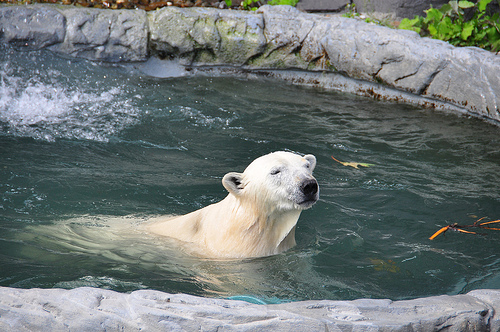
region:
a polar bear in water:
[14, 17, 488, 325]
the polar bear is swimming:
[36, 120, 356, 281]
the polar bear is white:
[89, 144, 331, 265]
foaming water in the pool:
[3, 51, 159, 166]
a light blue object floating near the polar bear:
[217, 275, 298, 313]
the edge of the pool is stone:
[18, 0, 480, 109]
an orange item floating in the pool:
[412, 196, 499, 261]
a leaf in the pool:
[330, 144, 379, 176]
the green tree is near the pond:
[382, 1, 497, 41]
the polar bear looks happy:
[195, 130, 349, 227]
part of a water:
[167, 102, 214, 154]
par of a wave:
[360, 249, 392, 294]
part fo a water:
[363, 235, 396, 270]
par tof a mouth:
[293, 185, 310, 205]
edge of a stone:
[367, 291, 392, 317]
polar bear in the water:
[177, 122, 338, 268]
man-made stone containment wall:
[180, 2, 360, 73]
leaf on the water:
[325, 141, 371, 171]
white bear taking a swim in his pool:
[70, 96, 360, 283]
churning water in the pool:
[0, 61, 125, 138]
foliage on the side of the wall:
[397, 0, 497, 40]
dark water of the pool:
[322, 130, 477, 201]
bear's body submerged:
[55, 197, 175, 263]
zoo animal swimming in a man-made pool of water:
[0, 0, 491, 320]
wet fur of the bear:
[228, 218, 308, 256]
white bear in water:
[148, 129, 433, 317]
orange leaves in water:
[408, 213, 453, 253]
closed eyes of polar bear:
[252, 163, 319, 180]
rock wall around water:
[21, 6, 499, 101]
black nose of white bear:
[290, 174, 327, 206]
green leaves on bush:
[415, 3, 487, 58]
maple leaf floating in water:
[326, 143, 383, 182]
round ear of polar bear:
[212, 146, 252, 192]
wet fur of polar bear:
[214, 209, 275, 256]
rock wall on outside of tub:
[306, 3, 445, 34]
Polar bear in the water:
[157, 151, 317, 255]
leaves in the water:
[415, 203, 492, 245]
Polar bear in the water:
[126, 196, 230, 261]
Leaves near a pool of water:
[405, 13, 498, 58]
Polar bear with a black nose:
[287, 173, 319, 213]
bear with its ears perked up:
[217, 146, 326, 202]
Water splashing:
[24, 59, 116, 149]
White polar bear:
[218, 163, 332, 243]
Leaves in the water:
[323, 132, 415, 229]